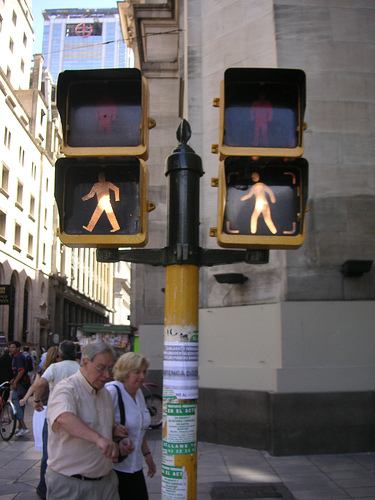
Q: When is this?
A: Daytime.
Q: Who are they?
A: Pedestrians.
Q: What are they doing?
A: Walking.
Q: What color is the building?
A: Gray.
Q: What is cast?
A: Shadow.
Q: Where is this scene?
A: On a sidewalk.